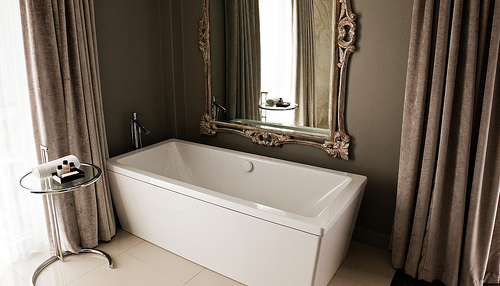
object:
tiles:
[0, 230, 397, 286]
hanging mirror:
[208, 0, 338, 137]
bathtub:
[106, 139, 367, 286]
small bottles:
[57, 161, 75, 177]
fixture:
[131, 112, 151, 148]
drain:
[243, 161, 253, 172]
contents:
[34, 155, 86, 184]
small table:
[19, 162, 111, 286]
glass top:
[19, 162, 102, 194]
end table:
[19, 163, 113, 286]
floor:
[0, 229, 396, 286]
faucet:
[131, 112, 150, 149]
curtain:
[15, 0, 114, 252]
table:
[19, 163, 113, 286]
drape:
[390, 0, 500, 286]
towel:
[32, 155, 80, 179]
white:
[197, 223, 272, 251]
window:
[0, 0, 51, 280]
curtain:
[390, 0, 500, 286]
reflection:
[258, 98, 298, 111]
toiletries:
[52, 160, 86, 184]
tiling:
[0, 231, 396, 286]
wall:
[96, 0, 412, 235]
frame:
[197, 0, 356, 161]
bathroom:
[0, 0, 500, 286]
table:
[258, 101, 299, 110]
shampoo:
[56, 160, 74, 177]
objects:
[57, 160, 79, 178]